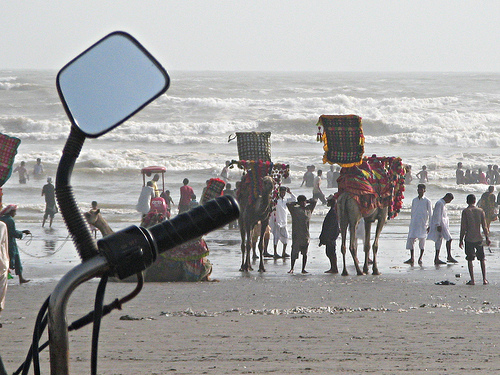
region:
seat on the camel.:
[312, 101, 385, 178]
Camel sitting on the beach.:
[76, 198, 221, 288]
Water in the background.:
[2, 68, 498, 214]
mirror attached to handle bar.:
[52, 25, 167, 141]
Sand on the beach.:
[0, 222, 497, 374]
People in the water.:
[12, 150, 44, 185]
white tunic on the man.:
[407, 184, 434, 251]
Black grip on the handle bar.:
[107, 189, 245, 278]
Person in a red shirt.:
[177, 170, 198, 212]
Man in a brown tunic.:
[282, 189, 319, 261]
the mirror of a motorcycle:
[41, 38, 165, 126]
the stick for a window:
[47, 121, 98, 239]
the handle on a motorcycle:
[152, 196, 236, 254]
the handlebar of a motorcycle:
[34, 255, 102, 363]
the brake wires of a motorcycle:
[18, 318, 73, 368]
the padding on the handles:
[185, 182, 223, 234]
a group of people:
[275, 175, 410, 249]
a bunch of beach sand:
[255, 291, 369, 361]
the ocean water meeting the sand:
[207, 242, 237, 269]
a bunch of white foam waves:
[215, 85, 273, 120]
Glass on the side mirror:
[75, 58, 143, 101]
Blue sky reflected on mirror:
[93, 67, 139, 100]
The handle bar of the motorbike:
[172, 219, 202, 231]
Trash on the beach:
[274, 308, 322, 313]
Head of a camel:
[88, 210, 100, 221]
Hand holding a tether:
[25, 231, 31, 235]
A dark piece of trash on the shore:
[438, 280, 449, 283]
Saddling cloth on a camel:
[185, 241, 201, 271]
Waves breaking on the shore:
[91, 152, 133, 168]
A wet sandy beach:
[339, 344, 391, 374]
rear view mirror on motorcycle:
[37, 25, 178, 254]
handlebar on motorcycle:
[94, 186, 265, 281]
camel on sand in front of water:
[212, 128, 290, 277]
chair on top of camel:
[302, 108, 382, 171]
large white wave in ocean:
[148, 109, 452, 141]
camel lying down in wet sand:
[80, 188, 233, 297]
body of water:
[0, 63, 471, 196]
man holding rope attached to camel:
[2, 198, 222, 293]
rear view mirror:
[52, 30, 168, 257]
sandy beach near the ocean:
[1, 277, 496, 368]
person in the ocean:
[13, 161, 30, 184]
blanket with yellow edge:
[317, 114, 364, 169]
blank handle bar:
[102, 194, 244, 277]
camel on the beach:
[335, 191, 387, 276]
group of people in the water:
[454, 162, 498, 186]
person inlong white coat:
[136, 180, 156, 212]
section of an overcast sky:
[4, 1, 496, 73]